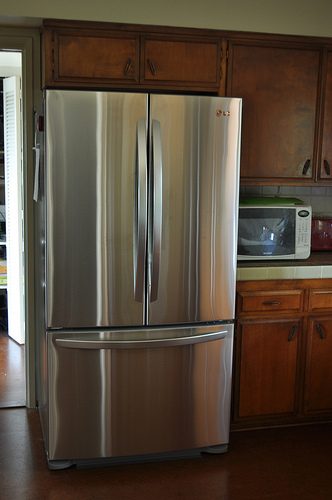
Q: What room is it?
A: It is a kitchen.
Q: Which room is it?
A: It is a kitchen.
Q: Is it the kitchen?
A: Yes, it is the kitchen.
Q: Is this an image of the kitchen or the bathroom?
A: It is showing the kitchen.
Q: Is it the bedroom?
A: No, it is the kitchen.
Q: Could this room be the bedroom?
A: No, it is the kitchen.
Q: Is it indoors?
A: Yes, it is indoors.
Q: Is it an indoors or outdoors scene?
A: It is indoors.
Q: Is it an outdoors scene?
A: No, it is indoors.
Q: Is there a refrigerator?
A: Yes, there is a refrigerator.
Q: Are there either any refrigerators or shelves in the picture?
A: Yes, there is a refrigerator.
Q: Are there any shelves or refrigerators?
A: Yes, there is a refrigerator.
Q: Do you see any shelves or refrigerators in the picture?
A: Yes, there is a refrigerator.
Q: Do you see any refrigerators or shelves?
A: Yes, there is a refrigerator.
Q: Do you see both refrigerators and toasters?
A: No, there is a refrigerator but no toasters.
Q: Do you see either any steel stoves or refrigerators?
A: Yes, there is a steel refrigerator.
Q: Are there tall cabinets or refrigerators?
A: Yes, there is a tall refrigerator.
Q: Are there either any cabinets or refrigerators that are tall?
A: Yes, the refrigerator is tall.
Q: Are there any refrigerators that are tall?
A: Yes, there is a tall refrigerator.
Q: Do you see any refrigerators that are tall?
A: Yes, there is a tall refrigerator.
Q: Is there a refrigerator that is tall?
A: Yes, there is a refrigerator that is tall.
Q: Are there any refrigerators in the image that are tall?
A: Yes, there is a refrigerator that is tall.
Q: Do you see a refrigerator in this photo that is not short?
A: Yes, there is a tall refrigerator.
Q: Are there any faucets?
A: No, there are no faucets.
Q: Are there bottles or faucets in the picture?
A: No, there are no faucets or bottles.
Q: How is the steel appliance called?
A: The appliance is a refrigerator.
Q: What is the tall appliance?
A: The appliance is a refrigerator.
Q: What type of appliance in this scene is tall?
A: The appliance is a refrigerator.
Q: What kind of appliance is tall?
A: The appliance is a refrigerator.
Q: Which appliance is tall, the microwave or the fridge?
A: The fridge is tall.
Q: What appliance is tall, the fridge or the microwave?
A: The fridge is tall.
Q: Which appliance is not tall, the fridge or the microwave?
A: The microwave is not tall.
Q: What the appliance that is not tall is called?
A: The appliance is a microwave.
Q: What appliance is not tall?
A: The appliance is a microwave.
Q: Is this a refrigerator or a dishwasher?
A: This is a refrigerator.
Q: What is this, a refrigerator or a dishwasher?
A: This is a refrigerator.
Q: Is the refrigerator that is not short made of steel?
A: Yes, the freezer is made of steel.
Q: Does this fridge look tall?
A: Yes, the fridge is tall.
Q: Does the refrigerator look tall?
A: Yes, the refrigerator is tall.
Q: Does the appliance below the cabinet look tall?
A: Yes, the refrigerator is tall.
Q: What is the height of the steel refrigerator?
A: The fridge is tall.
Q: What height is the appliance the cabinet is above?
A: The fridge is tall.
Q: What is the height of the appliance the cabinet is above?
A: The fridge is tall.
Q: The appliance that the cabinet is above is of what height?
A: The fridge is tall.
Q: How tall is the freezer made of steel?
A: The refrigerator is tall.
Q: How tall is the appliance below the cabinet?
A: The refrigerator is tall.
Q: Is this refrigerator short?
A: No, the refrigerator is tall.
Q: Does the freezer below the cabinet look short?
A: No, the freezer is tall.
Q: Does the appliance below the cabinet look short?
A: No, the freezer is tall.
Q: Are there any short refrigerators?
A: No, there is a refrigerator but it is tall.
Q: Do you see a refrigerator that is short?
A: No, there is a refrigerator but it is tall.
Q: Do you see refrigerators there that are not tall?
A: No, there is a refrigerator but it is tall.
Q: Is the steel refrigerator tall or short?
A: The freezer is tall.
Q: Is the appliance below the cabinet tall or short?
A: The freezer is tall.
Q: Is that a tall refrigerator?
A: Yes, that is a tall refrigerator.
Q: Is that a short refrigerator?
A: No, that is a tall refrigerator.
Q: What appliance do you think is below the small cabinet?
A: The appliance is a refrigerator.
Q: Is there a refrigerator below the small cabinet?
A: Yes, there is a refrigerator below the cabinet.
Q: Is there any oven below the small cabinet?
A: No, there is a refrigerator below the cabinet.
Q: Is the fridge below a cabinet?
A: Yes, the fridge is below a cabinet.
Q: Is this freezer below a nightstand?
A: No, the freezer is below a cabinet.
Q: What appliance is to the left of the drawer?
A: The appliance is a refrigerator.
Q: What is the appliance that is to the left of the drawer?
A: The appliance is a refrigerator.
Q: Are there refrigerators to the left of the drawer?
A: Yes, there is a refrigerator to the left of the drawer.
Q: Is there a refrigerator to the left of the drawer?
A: Yes, there is a refrigerator to the left of the drawer.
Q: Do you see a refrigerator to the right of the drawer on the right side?
A: No, the refrigerator is to the left of the drawer.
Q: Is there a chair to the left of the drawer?
A: No, there is a refrigerator to the left of the drawer.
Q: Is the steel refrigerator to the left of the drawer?
A: Yes, the fridge is to the left of the drawer.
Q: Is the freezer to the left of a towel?
A: No, the freezer is to the left of the drawer.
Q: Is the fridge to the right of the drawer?
A: No, the fridge is to the left of the drawer.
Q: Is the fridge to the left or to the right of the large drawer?
A: The fridge is to the left of the drawer.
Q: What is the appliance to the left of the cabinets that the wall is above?
A: The appliance is a refrigerator.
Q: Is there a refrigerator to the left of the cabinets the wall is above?
A: Yes, there is a refrigerator to the left of the cabinets.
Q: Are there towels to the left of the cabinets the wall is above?
A: No, there is a refrigerator to the left of the cabinets.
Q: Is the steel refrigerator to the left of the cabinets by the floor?
A: Yes, the freezer is to the left of the cabinets.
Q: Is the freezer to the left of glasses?
A: No, the freezer is to the left of the cabinets.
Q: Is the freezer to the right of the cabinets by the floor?
A: No, the freezer is to the left of the cabinets.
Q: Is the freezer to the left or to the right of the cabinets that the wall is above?
A: The freezer is to the left of the cabinets.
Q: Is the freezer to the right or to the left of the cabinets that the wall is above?
A: The freezer is to the left of the cabinets.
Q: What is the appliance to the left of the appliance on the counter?
A: The appliance is a refrigerator.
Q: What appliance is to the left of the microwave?
A: The appliance is a refrigerator.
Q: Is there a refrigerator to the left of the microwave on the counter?
A: Yes, there is a refrigerator to the left of the microwave.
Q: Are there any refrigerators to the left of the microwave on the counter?
A: Yes, there is a refrigerator to the left of the microwave.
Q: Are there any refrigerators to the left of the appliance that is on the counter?
A: Yes, there is a refrigerator to the left of the microwave.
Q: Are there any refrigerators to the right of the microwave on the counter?
A: No, the refrigerator is to the left of the microwave.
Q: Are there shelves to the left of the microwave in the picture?
A: No, there is a refrigerator to the left of the microwave.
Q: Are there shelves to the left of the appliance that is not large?
A: No, there is a refrigerator to the left of the microwave.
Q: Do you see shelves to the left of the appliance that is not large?
A: No, there is a refrigerator to the left of the microwave.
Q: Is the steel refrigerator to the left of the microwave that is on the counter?
A: Yes, the freezer is to the left of the microwave.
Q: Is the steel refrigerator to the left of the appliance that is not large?
A: Yes, the freezer is to the left of the microwave.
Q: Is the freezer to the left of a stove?
A: No, the freezer is to the left of the microwave.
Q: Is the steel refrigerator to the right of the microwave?
A: No, the refrigerator is to the left of the microwave.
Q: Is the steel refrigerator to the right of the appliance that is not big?
A: No, the refrigerator is to the left of the microwave.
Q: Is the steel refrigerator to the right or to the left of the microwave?
A: The refrigerator is to the left of the microwave.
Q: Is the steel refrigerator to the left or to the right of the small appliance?
A: The refrigerator is to the left of the microwave.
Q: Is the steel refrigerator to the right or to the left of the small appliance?
A: The refrigerator is to the left of the microwave.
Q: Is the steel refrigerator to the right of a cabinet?
A: No, the freezer is to the left of a cabinet.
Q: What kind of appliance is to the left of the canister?
A: The appliance is a refrigerator.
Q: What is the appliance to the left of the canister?
A: The appliance is a refrigerator.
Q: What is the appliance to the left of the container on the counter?
A: The appliance is a refrigerator.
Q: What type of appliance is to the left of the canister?
A: The appliance is a refrigerator.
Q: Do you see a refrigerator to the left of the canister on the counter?
A: Yes, there is a refrigerator to the left of the canister.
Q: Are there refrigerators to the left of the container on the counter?
A: Yes, there is a refrigerator to the left of the canister.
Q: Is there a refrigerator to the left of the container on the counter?
A: Yes, there is a refrigerator to the left of the canister.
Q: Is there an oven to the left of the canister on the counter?
A: No, there is a refrigerator to the left of the canister.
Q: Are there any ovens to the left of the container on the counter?
A: No, there is a refrigerator to the left of the canister.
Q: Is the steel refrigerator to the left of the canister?
A: Yes, the freezer is to the left of the canister.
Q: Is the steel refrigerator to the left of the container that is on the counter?
A: Yes, the freezer is to the left of the canister.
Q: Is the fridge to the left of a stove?
A: No, the fridge is to the left of the canister.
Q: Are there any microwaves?
A: Yes, there is a microwave.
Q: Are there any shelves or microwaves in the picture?
A: Yes, there is a microwave.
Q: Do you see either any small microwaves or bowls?
A: Yes, there is a small microwave.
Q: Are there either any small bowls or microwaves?
A: Yes, there is a small microwave.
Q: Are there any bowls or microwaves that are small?
A: Yes, the microwave is small.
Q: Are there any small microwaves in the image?
A: Yes, there is a small microwave.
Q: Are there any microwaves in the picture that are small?
A: Yes, there is a microwave that is small.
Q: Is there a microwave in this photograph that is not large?
A: Yes, there is a small microwave.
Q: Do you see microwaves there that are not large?
A: Yes, there is a small microwave.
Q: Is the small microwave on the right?
A: Yes, the microwave is on the right of the image.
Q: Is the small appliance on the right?
A: Yes, the microwave is on the right of the image.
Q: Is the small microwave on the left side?
A: No, the microwave is on the right of the image.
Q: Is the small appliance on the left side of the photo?
A: No, the microwave is on the right of the image.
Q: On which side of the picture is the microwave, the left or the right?
A: The microwave is on the right of the image.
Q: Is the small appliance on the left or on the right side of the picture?
A: The microwave is on the right of the image.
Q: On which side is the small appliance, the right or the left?
A: The microwave is on the right of the image.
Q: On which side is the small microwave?
A: The microwave is on the right of the image.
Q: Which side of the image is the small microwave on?
A: The microwave is on the right of the image.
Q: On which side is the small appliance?
A: The microwave is on the right of the image.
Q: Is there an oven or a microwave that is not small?
A: No, there is a microwave but it is small.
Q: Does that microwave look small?
A: Yes, the microwave is small.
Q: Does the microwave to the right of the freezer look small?
A: Yes, the microwave is small.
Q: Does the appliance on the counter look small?
A: Yes, the microwave is small.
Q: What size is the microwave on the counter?
A: The microwave is small.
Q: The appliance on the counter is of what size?
A: The microwave is small.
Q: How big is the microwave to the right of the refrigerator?
A: The microwave is small.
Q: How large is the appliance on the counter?
A: The microwave is small.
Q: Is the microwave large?
A: No, the microwave is small.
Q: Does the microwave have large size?
A: No, the microwave is small.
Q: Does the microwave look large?
A: No, the microwave is small.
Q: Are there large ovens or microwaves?
A: No, there is a microwave but it is small.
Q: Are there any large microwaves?
A: No, there is a microwave but it is small.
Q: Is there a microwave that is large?
A: No, there is a microwave but it is small.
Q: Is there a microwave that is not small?
A: No, there is a microwave but it is small.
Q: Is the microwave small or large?
A: The microwave is small.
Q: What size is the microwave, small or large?
A: The microwave is small.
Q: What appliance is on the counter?
A: The appliance is a microwave.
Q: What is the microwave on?
A: The microwave is on the counter.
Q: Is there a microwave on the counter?
A: Yes, there is a microwave on the counter.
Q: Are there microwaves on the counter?
A: Yes, there is a microwave on the counter.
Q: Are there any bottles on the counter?
A: No, there is a microwave on the counter.